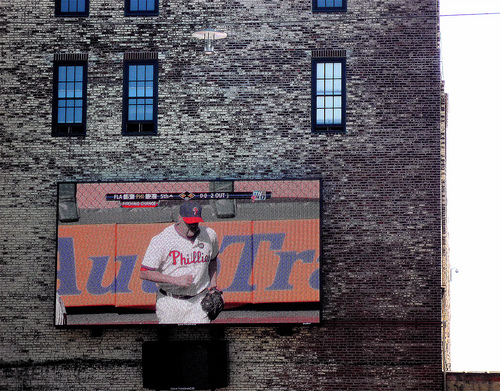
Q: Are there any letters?
A: Yes, there are letters.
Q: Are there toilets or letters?
A: Yes, there are letters.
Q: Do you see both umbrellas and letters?
A: No, there are letters but no umbrellas.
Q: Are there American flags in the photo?
A: No, there are no American flags.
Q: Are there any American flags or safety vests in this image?
A: No, there are no American flags or safety vests.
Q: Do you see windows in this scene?
A: Yes, there is a window.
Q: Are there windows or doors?
A: Yes, there is a window.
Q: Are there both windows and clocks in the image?
A: No, there is a window but no clocks.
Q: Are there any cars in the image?
A: No, there are no cars.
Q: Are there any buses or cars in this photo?
A: No, there are no cars or buses.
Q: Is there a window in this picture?
A: Yes, there is a window.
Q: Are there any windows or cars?
A: Yes, there is a window.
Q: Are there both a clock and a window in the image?
A: No, there is a window but no clocks.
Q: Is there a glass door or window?
A: Yes, there is a glass window.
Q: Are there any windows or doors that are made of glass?
A: Yes, the window is made of glass.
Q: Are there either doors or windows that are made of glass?
A: Yes, the window is made of glass.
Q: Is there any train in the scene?
A: No, there are no trains.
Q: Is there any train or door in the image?
A: No, there are no trains or doors.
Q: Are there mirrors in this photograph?
A: No, there are no mirrors.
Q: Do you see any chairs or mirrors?
A: No, there are no mirrors or chairs.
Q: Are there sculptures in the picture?
A: No, there are no sculptures.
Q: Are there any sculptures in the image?
A: No, there are no sculptures.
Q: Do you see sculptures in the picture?
A: No, there are no sculptures.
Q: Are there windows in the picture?
A: Yes, there is a window.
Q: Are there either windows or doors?
A: Yes, there is a window.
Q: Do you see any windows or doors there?
A: Yes, there is a window.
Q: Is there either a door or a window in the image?
A: Yes, there is a window.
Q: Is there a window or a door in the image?
A: Yes, there is a window.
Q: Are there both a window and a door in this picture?
A: No, there is a window but no doors.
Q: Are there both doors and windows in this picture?
A: No, there is a window but no doors.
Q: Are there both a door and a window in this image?
A: No, there is a window but no doors.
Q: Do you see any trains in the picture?
A: No, there are no trains.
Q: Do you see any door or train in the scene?
A: No, there are no trains or doors.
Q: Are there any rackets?
A: No, there are no rackets.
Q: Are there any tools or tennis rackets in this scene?
A: No, there are no tennis rackets or tools.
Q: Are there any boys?
A: No, there are no boys.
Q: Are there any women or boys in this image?
A: No, there are no boys or women.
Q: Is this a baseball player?
A: Yes, this is a baseball player.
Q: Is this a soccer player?
A: No, this is a baseball player.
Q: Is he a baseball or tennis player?
A: This is a baseball player.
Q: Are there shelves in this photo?
A: No, there are no shelves.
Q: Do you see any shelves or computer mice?
A: No, there are no shelves or computer mice.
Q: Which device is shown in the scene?
A: The device is a screen.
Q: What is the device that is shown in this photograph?
A: The device is a screen.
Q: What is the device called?
A: The device is a screen.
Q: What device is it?
A: The device is a screen.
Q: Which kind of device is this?
A: This is a screen.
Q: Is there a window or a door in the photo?
A: Yes, there is a window.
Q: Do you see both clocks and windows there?
A: No, there is a window but no clocks.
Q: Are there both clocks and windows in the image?
A: No, there is a window but no clocks.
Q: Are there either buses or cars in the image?
A: No, there are no buses or cars.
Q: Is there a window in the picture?
A: Yes, there is a window.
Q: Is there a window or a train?
A: Yes, there is a window.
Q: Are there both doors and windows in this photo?
A: No, there is a window but no doors.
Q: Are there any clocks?
A: No, there are no clocks.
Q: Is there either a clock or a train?
A: No, there are no clocks or trains.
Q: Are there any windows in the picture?
A: Yes, there is a window.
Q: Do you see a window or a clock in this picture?
A: Yes, there is a window.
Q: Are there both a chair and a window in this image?
A: No, there is a window but no chairs.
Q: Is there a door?
A: No, there are no doors.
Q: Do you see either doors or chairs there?
A: No, there are no doors or chairs.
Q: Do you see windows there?
A: Yes, there is a window.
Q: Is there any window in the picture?
A: Yes, there is a window.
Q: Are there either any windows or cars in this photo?
A: Yes, there is a window.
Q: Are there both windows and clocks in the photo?
A: No, there is a window but no clocks.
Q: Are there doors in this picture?
A: No, there are no doors.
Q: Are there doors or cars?
A: No, there are no doors or cars.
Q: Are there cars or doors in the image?
A: No, there are no doors or cars.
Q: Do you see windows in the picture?
A: Yes, there is a window.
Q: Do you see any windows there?
A: Yes, there is a window.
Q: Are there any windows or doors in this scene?
A: Yes, there is a window.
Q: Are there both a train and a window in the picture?
A: No, there is a window but no trains.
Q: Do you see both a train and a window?
A: No, there is a window but no trains.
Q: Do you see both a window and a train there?
A: No, there is a window but no trains.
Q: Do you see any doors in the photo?
A: No, there are no doors.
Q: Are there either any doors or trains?
A: No, there are no doors or trains.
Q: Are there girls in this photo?
A: No, there are no girls.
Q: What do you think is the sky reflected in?
A: The sky is reflected in the window.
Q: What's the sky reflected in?
A: The sky is reflected in the window.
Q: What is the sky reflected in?
A: The sky is reflected in the window.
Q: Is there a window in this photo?
A: Yes, there is a window.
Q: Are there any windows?
A: Yes, there is a window.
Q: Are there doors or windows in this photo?
A: Yes, there is a window.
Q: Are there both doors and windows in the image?
A: No, there is a window but no doors.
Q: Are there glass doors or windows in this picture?
A: Yes, there is a glass window.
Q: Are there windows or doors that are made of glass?
A: Yes, the window is made of glass.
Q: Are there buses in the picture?
A: No, there are no buses.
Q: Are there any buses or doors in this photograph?
A: No, there are no buses or doors.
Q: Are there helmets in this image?
A: No, there are no helmets.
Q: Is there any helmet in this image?
A: No, there are no helmets.